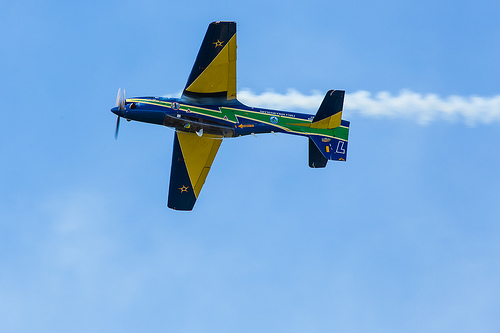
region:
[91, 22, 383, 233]
plane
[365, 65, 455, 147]
smoke from plane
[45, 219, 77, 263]
white clouds in blue sky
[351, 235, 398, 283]
white clouds in blue sky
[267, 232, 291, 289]
white clouds in blue sky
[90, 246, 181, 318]
white clouds in blue sky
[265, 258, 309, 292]
white clouds in blue sky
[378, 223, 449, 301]
white clouds in blue sky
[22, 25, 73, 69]
white clouds in blue sky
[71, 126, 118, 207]
white clouds in blue sky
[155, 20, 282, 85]
hand of the plane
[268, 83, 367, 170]
back part of the plane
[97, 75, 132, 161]
fan of the plane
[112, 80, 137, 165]
fan revolving ni air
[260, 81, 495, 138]
a white air in air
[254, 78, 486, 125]
a white smoke from plane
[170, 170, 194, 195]
a small star design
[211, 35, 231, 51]
a logo of flight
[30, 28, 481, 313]
a plane in air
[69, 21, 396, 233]
a flight flying in air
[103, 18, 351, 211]
plane in the sky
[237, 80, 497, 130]
white contrail coming off the plane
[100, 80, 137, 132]
propeller on the front of the plane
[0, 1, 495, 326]
bright blue sky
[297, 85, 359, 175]
tail of the plane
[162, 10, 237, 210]
two wings on either side of the plane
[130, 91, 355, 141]
green stripe on the plane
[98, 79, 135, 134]
nose of the plane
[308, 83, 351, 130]
black and yellow paint on the tail of the plane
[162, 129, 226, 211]
wing is black and yellow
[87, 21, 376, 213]
Multi colored airplane in the sky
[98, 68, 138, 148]
White propellor on the nose of the plane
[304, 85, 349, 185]
Two blue and yellow wings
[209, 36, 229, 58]
Yellow star on the wing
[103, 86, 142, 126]
Blue nose of airplane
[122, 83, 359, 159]
Green stripe on airplane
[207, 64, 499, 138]
White cloud of smoke behind plane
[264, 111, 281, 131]
Blue logo on airplane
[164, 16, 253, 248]
Two large blue and yellow wings on plane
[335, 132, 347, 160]
Blue number on wing of plane